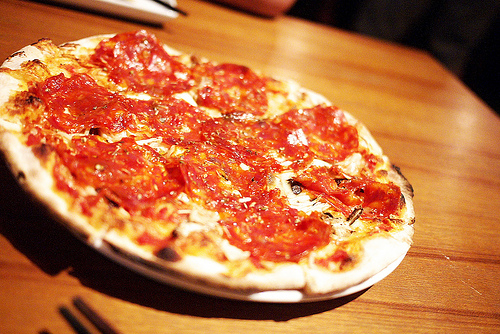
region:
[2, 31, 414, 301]
Whole pepperoni on a white plate.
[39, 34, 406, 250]
Pepperoni and cheese toppings on pizza.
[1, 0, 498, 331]
Pizza served in a restaurant.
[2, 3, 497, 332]
Pepperoni pizza served on a wooden table.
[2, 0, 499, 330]
Wooden dining table in pizza place.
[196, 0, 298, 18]
Customer's elbow on the table.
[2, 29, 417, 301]
Freshly cooked pizza on the table.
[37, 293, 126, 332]
Plastic silverware on the table.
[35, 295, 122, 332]
Plastic fork on the wooden table.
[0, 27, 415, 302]
Baked pepperoni and cheese small pizza.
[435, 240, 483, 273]
dark brown lines on the table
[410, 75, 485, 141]
shine on the table top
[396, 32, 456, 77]
edge of brown table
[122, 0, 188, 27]
edge of white plate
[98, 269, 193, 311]
shadow of round plate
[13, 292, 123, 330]
edge of forks on table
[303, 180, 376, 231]
small herb on plate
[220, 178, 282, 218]
bits of cheese on pizza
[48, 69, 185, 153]
red pepperoni slices on the pizza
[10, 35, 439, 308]
large pizza on round plate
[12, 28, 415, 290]
Pizza on a plate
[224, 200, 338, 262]
A piece of pepperoni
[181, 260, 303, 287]
Part of the crust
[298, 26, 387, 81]
A wood table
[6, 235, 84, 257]
A shadow from the plate and pizza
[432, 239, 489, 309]
A scratch in the wood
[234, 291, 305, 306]
A white plate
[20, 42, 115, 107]
Crust, pepperoni and cheese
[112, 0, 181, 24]
A white dish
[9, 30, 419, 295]
Pepperoni pizza with cheese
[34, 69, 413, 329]
pizza has red pepperoni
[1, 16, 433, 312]
Pizza on dish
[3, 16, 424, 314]
Dish under pizza is white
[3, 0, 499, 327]
Table is brown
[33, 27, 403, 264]
Tomato on pizza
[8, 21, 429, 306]
Crust pizza es thin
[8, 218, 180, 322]
Shadow of dish on table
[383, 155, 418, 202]
Crust is a little burned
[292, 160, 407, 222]
Slice of tomato on pizza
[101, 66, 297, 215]
Herbs on top of pizza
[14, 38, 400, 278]
Pizza has cheese under tomato